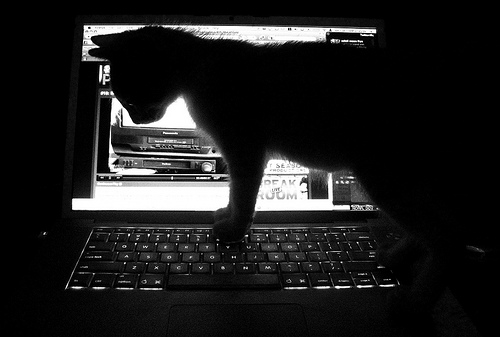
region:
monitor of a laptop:
[146, 131, 200, 179]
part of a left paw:
[219, 222, 241, 245]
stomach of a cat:
[273, 120, 331, 182]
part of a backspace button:
[205, 270, 258, 297]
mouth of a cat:
[136, 115, 163, 128]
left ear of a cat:
[86, 19, 126, 56]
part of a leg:
[234, 159, 255, 209]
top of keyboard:
[161, 232, 263, 279]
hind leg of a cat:
[357, 172, 405, 219]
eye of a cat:
[121, 82, 142, 107]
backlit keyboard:
[71, 216, 427, 300]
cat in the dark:
[80, 23, 492, 254]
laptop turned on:
[61, 20, 462, 312]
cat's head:
[68, 27, 245, 135]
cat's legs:
[198, 95, 295, 250]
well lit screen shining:
[69, 23, 235, 202]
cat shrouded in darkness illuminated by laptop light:
[81, 30, 424, 233]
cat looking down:
[76, 21, 498, 259]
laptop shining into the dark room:
[41, 14, 488, 311]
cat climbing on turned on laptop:
[37, 10, 479, 335]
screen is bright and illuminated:
[83, 101, 411, 242]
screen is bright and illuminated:
[81, 87, 298, 205]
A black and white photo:
[34, 18, 461, 298]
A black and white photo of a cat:
[79, 26, 388, 292]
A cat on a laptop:
[72, 28, 375, 299]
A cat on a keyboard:
[54, 27, 345, 253]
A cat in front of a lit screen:
[78, 26, 360, 255]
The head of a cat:
[72, 20, 194, 134]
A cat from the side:
[73, 20, 426, 233]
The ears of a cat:
[75, 23, 125, 69]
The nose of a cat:
[99, 83, 182, 138]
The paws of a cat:
[170, 187, 278, 245]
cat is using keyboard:
[63, 14, 462, 263]